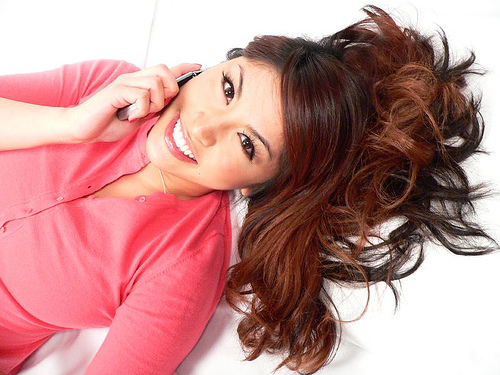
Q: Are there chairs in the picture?
A: No, there are no chairs.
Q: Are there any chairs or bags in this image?
A: No, there are no chairs or bags.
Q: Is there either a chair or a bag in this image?
A: No, there are no chairs or bags.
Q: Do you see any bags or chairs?
A: No, there are no chairs or bags.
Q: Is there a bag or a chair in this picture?
A: No, there are no chairs or bags.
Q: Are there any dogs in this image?
A: No, there are no dogs.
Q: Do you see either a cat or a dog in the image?
A: No, there are no dogs or cats.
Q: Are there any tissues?
A: No, there are no tissues.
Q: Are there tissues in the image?
A: No, there are no tissues.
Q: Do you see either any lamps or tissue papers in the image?
A: No, there are no tissue papers or lamps.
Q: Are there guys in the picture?
A: No, there are no guys.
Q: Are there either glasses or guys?
A: No, there are no guys or glasses.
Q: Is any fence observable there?
A: No, there are no fences.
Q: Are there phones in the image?
A: Yes, there is a phone.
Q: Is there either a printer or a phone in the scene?
A: Yes, there is a phone.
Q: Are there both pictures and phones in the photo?
A: No, there is a phone but no pictures.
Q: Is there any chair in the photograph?
A: No, there are no chairs.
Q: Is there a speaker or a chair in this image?
A: No, there are no chairs or speakers.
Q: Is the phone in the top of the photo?
A: Yes, the phone is in the top of the image.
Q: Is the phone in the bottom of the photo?
A: No, the phone is in the top of the image.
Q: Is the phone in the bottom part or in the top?
A: The phone is in the top of the image.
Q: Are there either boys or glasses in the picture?
A: No, there are no glasses or boys.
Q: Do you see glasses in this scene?
A: No, there are no glasses.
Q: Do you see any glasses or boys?
A: No, there are no glasses or boys.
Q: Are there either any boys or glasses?
A: No, there are no glasses or boys.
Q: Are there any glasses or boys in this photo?
A: No, there are no glasses or boys.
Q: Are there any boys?
A: No, there are no boys.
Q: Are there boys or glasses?
A: No, there are no boys or glasses.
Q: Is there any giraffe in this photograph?
A: No, there are no giraffes.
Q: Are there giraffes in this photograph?
A: No, there are no giraffes.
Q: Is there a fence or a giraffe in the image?
A: No, there are no giraffes or fences.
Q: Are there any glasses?
A: No, there are no glasses.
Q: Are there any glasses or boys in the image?
A: No, there are no glasses or boys.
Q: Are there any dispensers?
A: No, there are no dispensers.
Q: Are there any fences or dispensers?
A: No, there are no dispensers or fences.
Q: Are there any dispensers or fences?
A: No, there are no dispensers or fences.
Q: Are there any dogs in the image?
A: No, there are no dogs.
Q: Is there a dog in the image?
A: No, there are no dogs.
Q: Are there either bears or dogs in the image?
A: No, there are no dogs or bears.